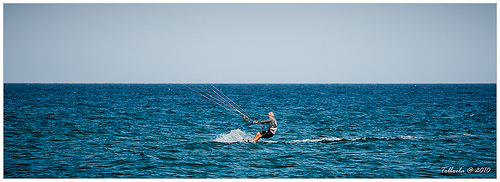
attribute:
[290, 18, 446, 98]
sky — blue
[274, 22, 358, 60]
clouds — white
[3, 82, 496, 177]
ocean — deep, blue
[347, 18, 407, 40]
clouds — white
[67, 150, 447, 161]
water — clear, blue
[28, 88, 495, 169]
water — clear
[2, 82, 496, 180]
water — blue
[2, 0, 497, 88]
sky — blue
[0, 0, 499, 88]
clouds — white